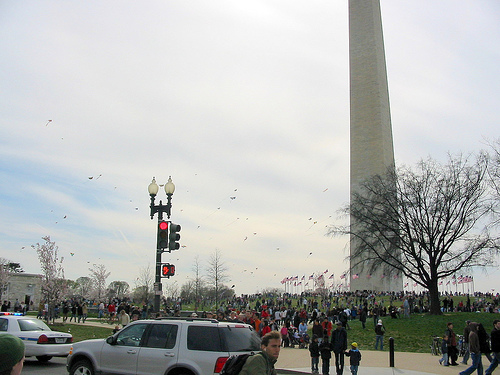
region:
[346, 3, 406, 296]
large cement monument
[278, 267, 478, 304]
american flags surrounding the monument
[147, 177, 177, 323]
elegant street lights by road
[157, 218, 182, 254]
stop light attached to street lamp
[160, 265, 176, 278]
cross walk sign on street light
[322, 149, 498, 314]
tree barren from any leaves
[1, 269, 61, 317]
building to the left of picture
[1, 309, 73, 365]
police car parked on side of road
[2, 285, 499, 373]
huge croud of people going to monument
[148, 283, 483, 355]
large gathering of people on green grass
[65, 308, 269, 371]
silver SUV parked in front of monument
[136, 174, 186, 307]
street lamps on metal street pole with traffic lights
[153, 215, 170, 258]
traffic light indicating red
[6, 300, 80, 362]
white police car withe lights flashing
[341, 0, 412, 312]
washington dc monumnet surrounded by flags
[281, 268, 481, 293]
american flags surrounding war monument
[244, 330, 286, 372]
man in foreground wearing green parka and white earbuds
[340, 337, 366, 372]
small child in blue coat amd yellow hat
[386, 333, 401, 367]
black metal pole on sidewalk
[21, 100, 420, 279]
birds flying in cloudy sky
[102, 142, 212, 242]
the traffic light is red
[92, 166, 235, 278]
lights are over the traffic light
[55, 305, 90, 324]
people are walking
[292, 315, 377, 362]
a man is walking with children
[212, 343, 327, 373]
a man has a backpack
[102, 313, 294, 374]
the suv is silver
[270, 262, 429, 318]
several american flags are waving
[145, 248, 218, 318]
the walk sign is illuminated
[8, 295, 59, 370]
a police car has its lights on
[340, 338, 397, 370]
the boy is wearing a yellow hat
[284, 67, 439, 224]
This is a tower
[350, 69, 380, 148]
This is a monument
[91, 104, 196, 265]
This is a light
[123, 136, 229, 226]
The light is white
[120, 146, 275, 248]
These are two lights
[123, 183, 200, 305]
This is a red light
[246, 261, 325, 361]
This is a crowd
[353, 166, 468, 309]
The tree is bare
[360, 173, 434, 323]
The tree has no leaves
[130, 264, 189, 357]
This is a car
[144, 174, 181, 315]
Lamp post with two traffic lights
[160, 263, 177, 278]
Black neon walking sign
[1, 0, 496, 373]
People in Washington, D.C.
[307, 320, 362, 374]
Adult with three children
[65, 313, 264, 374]
White SUV driving on the road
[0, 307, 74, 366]
White police car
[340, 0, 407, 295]
Washington monument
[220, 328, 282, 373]
Man wearing a black backpack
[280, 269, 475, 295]
Circle of American Flags at the base of a monument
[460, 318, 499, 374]
Two people walking on a sidewalk